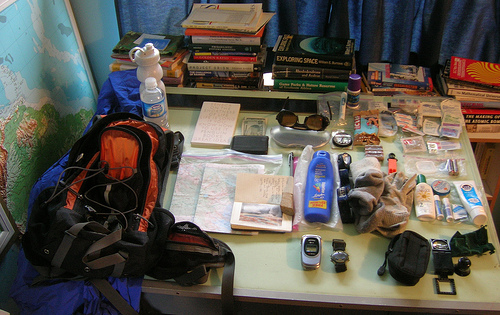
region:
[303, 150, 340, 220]
blue bottle of sunscreen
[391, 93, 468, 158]
parts of a first aid kit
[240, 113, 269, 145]
a stack of cash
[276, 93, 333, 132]
a pair of sunglasses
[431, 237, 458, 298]
a travel size compass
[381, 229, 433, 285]
black nylon camer case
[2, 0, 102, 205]
large map on wall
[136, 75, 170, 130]
plastic water bottle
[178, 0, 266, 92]
a stack of books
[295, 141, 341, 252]
This is a bottle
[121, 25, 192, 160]
This is a bottle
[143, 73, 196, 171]
This is a bottle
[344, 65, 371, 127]
This is a bottle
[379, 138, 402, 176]
This is a bottle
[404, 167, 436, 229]
This is a bottle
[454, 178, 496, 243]
This is a bottle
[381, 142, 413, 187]
This is a bottle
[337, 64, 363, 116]
This is a bottle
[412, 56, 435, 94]
This is a bottle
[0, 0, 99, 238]
the map turned sideways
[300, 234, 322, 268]
the phone on the desk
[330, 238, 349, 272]
the watch on the desk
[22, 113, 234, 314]
the backpack on the desk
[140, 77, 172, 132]
the bottled water on the desk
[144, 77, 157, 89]
the cap on the water bottle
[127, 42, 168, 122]
the water bottle on the desk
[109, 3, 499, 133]
the piles of books near the desk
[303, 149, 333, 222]
the blue bottle on the desk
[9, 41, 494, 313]
the clutter on the desk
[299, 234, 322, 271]
a cell phone is on the table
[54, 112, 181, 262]
a backpackt is on the table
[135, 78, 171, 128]
a water bottle is on the table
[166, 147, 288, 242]
a map is on the table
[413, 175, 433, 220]
a bottle is on the table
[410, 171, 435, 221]
the bottle is made of plastic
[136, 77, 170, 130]
the bottle is made of plastic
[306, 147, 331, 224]
the bottle is made of plastic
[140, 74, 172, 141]
a bottle on the table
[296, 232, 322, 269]
a phone on the table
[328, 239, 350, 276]
a wrist watch on the table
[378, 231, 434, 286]
a small bag on the table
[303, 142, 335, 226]
a large blue bottle on the table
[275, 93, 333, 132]
a pair of sunglasses on the table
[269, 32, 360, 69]
a book called exploring space on the table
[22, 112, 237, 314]
an orange and black on the table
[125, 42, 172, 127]
a large bottle on the table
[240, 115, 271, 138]
a set of dollar bills on the table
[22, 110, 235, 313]
an orange and black backpack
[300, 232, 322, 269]
a silver and black cell phone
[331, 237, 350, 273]
a watch with a black band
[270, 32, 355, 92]
a small stack of books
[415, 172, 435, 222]
a bottle off sunscreen with a green lid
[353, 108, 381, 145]
a bagged snack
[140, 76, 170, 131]
a bottle of water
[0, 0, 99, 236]
a large framed map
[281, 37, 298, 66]
a book on the table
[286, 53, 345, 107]
a book on the table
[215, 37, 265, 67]
a book on the table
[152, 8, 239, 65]
a book on the table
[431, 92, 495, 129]
a book on the table